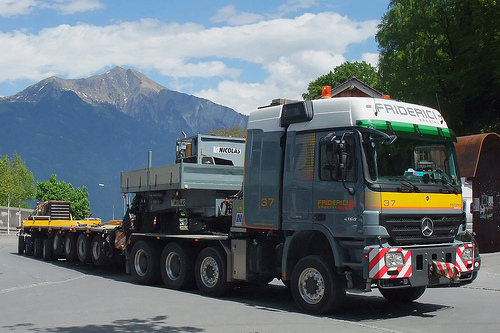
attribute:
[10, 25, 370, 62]
clouds — white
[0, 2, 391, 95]
sky — blue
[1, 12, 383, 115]
clouds — white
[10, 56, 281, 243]
mountain — distant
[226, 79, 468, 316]
truck — grey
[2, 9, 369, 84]
clouds — white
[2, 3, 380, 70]
sky — blue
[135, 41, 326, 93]
sky — blue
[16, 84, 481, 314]
truck — grey in color, grey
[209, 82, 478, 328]
truck — grey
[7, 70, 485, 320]
truck — grey, white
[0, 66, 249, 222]
mountain — distant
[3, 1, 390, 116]
clouds — white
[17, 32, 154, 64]
clouds — white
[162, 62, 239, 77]
clouds — white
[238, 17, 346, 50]
clouds — white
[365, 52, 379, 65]
clouds — white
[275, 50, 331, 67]
clouds — white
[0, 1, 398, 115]
sky — blue, cloudy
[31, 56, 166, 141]
mountain — distant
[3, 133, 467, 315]
truck — green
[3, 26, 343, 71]
clouds — white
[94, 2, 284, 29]
sky — blue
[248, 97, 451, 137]
top — green, white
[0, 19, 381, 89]
clouds — white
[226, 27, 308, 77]
clouds — white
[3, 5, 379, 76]
sky — blue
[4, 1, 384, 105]
sky — blue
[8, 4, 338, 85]
clouds — white